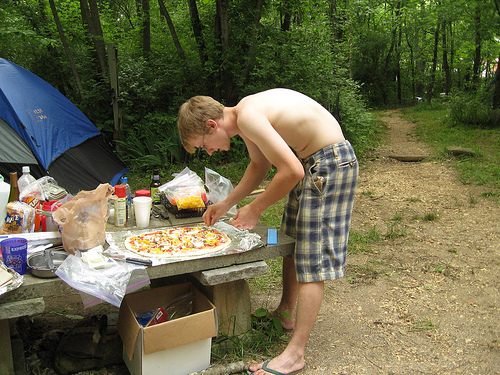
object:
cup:
[0, 236, 29, 275]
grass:
[410, 319, 434, 333]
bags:
[53, 244, 134, 308]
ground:
[0, 109, 499, 374]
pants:
[277, 139, 361, 284]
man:
[177, 85, 358, 375]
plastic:
[53, 247, 131, 310]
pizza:
[122, 226, 231, 258]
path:
[352, 101, 499, 374]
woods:
[0, 1, 499, 182]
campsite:
[0, 56, 360, 374]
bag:
[50, 182, 112, 255]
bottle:
[151, 167, 160, 204]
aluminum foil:
[103, 217, 264, 267]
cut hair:
[175, 94, 226, 155]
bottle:
[16, 166, 37, 193]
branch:
[186, 1, 210, 67]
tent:
[0, 55, 104, 176]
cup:
[130, 195, 151, 227]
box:
[113, 42, 221, 282]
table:
[0, 200, 295, 375]